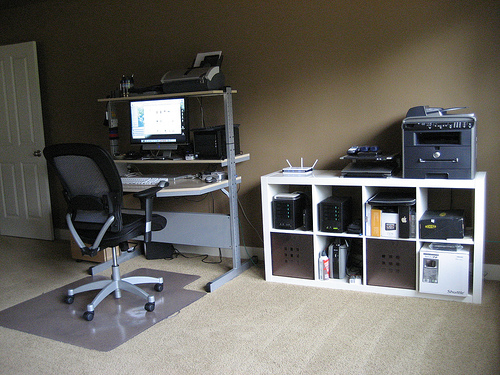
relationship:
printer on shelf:
[398, 103, 478, 178] [258, 163, 490, 294]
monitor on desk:
[127, 94, 189, 157] [91, 87, 258, 291]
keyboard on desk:
[117, 176, 171, 186] [108, 83, 253, 284]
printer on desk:
[161, 50, 226, 93] [91, 87, 258, 291]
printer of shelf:
[398, 103, 478, 178] [259, 160, 494, 303]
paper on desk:
[420, 206, 465, 238] [259, 167, 486, 302]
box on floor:
[354, 231, 423, 298] [1, 225, 496, 373]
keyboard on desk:
[123, 176, 170, 186] [91, 87, 258, 291]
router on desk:
[271, 155, 333, 177] [60, 136, 243, 277]